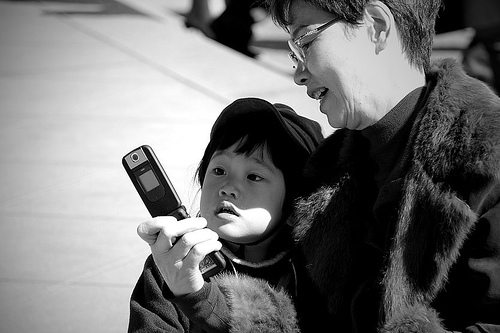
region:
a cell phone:
[125, 144, 226, 274]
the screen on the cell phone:
[135, 170, 158, 191]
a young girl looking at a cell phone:
[129, 85, 296, 315]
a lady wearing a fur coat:
[266, 9, 495, 288]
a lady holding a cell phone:
[98, 5, 494, 325]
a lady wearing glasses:
[271, 10, 452, 114]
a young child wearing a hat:
[199, 87, 334, 254]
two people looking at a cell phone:
[111, 0, 497, 330]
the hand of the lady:
[121, 212, 229, 311]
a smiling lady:
[271, 6, 471, 133]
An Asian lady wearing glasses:
[274, 0, 436, 150]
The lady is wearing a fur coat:
[288, 42, 469, 277]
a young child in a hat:
[186, 95, 318, 282]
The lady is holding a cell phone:
[150, 50, 383, 307]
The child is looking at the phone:
[124, 152, 254, 291]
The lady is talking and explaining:
[284, 35, 361, 145]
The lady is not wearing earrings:
[368, 23, 395, 67]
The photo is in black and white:
[31, 38, 436, 302]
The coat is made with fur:
[412, 173, 468, 298]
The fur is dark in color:
[408, 114, 465, 306]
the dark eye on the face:
[210, 163, 225, 176]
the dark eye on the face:
[246, 171, 261, 181]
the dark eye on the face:
[300, 38, 317, 50]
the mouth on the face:
[215, 201, 239, 219]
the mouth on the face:
[306, 86, 329, 103]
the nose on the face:
[218, 168, 242, 197]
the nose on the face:
[292, 51, 310, 83]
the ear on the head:
[362, 3, 389, 45]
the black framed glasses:
[283, 13, 345, 66]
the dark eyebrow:
[210, 148, 234, 162]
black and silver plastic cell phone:
[117, 140, 227, 281]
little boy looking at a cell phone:
[122, 92, 326, 332]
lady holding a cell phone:
[119, 0, 497, 332]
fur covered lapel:
[277, 47, 497, 331]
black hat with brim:
[202, 94, 324, 159]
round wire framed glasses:
[284, 15, 351, 62]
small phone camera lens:
[129, 149, 141, 164]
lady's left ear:
[361, 0, 398, 54]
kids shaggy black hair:
[185, 124, 305, 206]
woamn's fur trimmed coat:
[158, 57, 496, 332]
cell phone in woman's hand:
[116, 144, 224, 278]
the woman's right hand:
[133, 214, 223, 290]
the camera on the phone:
[129, 150, 142, 163]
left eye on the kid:
[243, 171, 264, 186]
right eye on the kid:
[202, 160, 227, 179]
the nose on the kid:
[218, 174, 242, 200]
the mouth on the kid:
[216, 199, 240, 220]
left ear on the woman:
[363, 0, 399, 51]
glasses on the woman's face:
[286, 15, 344, 59]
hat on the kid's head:
[211, 94, 321, 151]